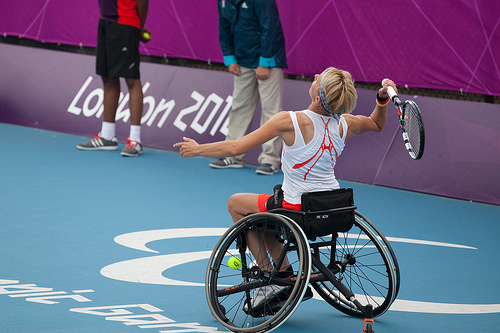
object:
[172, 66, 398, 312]
woman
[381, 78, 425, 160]
racket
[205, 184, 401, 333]
wheelchair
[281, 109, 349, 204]
tank top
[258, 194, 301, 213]
shorts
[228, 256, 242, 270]
ball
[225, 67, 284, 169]
pants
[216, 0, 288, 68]
jacket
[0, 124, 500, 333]
floor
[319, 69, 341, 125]
headband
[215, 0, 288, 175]
umpire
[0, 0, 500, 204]
background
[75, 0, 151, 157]
ball runner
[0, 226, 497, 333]
lettering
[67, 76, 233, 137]
london 2010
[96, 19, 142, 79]
shorts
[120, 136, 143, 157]
sneakers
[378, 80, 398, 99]
hand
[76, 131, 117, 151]
shoe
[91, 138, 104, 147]
stripes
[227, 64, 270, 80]
hands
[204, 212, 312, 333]
wheel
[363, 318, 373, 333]
wheel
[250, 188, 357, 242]
seat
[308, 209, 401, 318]
wheels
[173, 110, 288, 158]
arms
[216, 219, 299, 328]
spokes